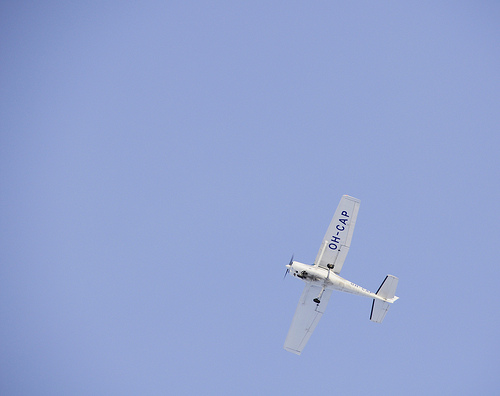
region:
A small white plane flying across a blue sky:
[256, 177, 407, 359]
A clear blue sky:
[18, 177, 279, 381]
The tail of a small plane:
[365, 271, 398, 321]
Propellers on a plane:
[277, 251, 293, 276]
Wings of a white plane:
[276, 191, 359, 358]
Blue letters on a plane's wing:
[325, 206, 351, 258]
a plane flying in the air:
[219, 165, 399, 339]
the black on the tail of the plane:
[373, 272, 388, 294]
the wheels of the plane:
[304, 257, 344, 305]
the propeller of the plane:
[281, 248, 301, 281]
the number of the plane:
[325, 203, 359, 259]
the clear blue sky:
[56, 93, 210, 230]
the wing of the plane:
[280, 301, 332, 368]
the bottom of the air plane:
[274, 232, 394, 337]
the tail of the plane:
[392, 293, 397, 304]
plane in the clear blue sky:
[39, 153, 452, 358]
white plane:
[266, 181, 405, 350]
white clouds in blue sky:
[64, 70, 114, 103]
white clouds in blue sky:
[58, 134, 97, 164]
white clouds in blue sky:
[84, 296, 129, 336]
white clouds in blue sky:
[153, 171, 214, 207]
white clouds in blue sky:
[377, 96, 445, 149]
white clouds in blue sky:
[419, 311, 466, 342]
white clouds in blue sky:
[134, 242, 178, 265]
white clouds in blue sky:
[198, 140, 246, 195]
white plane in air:
[274, 191, 401, 351]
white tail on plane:
[371, 275, 401, 325]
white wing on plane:
[321, 192, 361, 274]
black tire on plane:
[313, 295, 323, 305]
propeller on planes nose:
[279, 253, 295, 275]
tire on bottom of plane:
[300, 270, 313, 279]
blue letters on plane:
[326, 210, 351, 251]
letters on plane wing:
[328, 210, 349, 250]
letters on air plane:
[348, 277, 375, 299]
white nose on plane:
[286, 262, 291, 269]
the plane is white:
[253, 190, 416, 376]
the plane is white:
[263, 171, 422, 376]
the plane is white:
[254, 178, 409, 355]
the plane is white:
[259, 169, 411, 369]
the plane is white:
[258, 163, 410, 377]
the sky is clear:
[109, 215, 239, 362]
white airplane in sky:
[276, 188, 408, 363]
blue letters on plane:
[326, 205, 354, 264]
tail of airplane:
[353, 260, 405, 334]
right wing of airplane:
[311, 184, 363, 274]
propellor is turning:
[278, 254, 295, 278]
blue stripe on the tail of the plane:
[369, 272, 390, 320]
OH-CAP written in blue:
[322, 208, 352, 253]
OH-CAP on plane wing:
[327, 208, 351, 249]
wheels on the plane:
[310, 263, 334, 304]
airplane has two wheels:
[310, 257, 337, 309]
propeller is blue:
[277, 251, 297, 276]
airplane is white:
[284, 193, 398, 356]